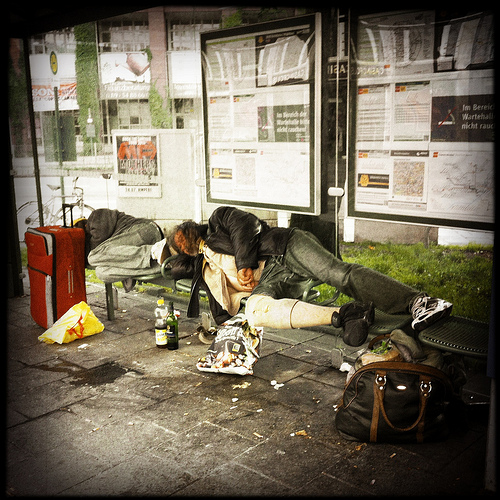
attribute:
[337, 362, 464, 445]
bag — black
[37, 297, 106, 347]
bag — plastic, yellow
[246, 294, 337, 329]
prostetic — fake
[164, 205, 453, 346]
vagabond — sleeping, asleep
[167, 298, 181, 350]
bottle — green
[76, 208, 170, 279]
hobo — laying, sleeping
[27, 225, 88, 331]
bag — red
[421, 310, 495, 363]
bench — silver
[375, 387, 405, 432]
handle — brown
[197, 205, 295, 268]
jacket — black, leather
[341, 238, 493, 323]
grass — green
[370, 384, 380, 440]
trim — brown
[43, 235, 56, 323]
trim — gray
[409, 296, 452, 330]
shoe — white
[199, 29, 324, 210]
poster — framed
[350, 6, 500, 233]
poster — framed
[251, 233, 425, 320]
jeans — black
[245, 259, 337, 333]
leg — prostetic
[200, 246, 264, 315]
shirt — cream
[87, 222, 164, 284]
pants — grey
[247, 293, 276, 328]
knee — bandaged